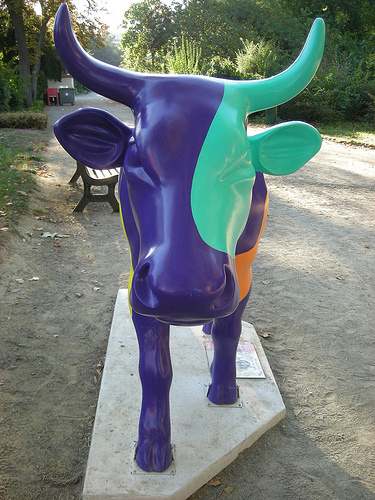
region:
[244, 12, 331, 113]
bullhorn on a bull statue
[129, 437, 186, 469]
hoove of a bull statue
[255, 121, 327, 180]
ear of a bull statue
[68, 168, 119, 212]
Park bench behind the bull statue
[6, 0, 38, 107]
trunk of a tall tree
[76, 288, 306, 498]
concrete foundation of a statue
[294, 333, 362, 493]
sand on the ground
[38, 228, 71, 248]
leaves fallen from the trees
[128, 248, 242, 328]
nose on the face of a bull statue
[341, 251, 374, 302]
tracks of something made in the sand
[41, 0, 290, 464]
Multi-colored fake bull statue.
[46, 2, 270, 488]
The fake bull is predominantly purple.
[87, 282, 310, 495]
Slab of concrete the statue is on.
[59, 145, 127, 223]
Wooden bench behind the statue.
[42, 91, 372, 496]
The road is made of dirt.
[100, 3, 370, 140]
Trees behind the statue are green.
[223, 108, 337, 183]
The ear on the right is teal.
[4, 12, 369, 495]
Photo taken during the day.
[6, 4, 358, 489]
Nobody shown in the picture.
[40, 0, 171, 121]
The horn on the left is purple.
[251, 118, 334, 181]
a teal ear on the bull statue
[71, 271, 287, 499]
the white base of a statue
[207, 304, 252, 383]
a purple leg of the bull statue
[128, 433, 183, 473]
a purple hoof of the bull statue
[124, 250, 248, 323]
a purple nose of the bull statue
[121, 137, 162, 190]
the eye of the bull statue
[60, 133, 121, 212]
a park bench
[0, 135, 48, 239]
a patch of green grass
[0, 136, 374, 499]
a brown dirt path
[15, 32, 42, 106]
the trunk of a tree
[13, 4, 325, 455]
a cow statue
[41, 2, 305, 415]
a cow statue outside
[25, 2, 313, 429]
a cow statue on dirt path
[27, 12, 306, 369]
blue green purple orange yellow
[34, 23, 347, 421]
purple green orange yellow cow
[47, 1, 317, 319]
a statue cow painted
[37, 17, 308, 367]
a painted statue cow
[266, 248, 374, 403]
a dirt covered ground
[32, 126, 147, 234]
a bench behind statue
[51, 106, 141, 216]
a bench in dirt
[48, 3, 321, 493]
Multi-colored bull standing on white stand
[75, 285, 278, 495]
White stand sitting on ground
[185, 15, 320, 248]
Aqua color of bull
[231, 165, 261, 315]
Orange part of bull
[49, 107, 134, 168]
Right ear of bull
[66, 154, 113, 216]
Wood bench sitting on the side of the road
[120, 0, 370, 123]
Tall trees in the background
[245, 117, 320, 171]
Left ear of bull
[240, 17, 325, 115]
Left horn of bull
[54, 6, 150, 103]
right horn of bull